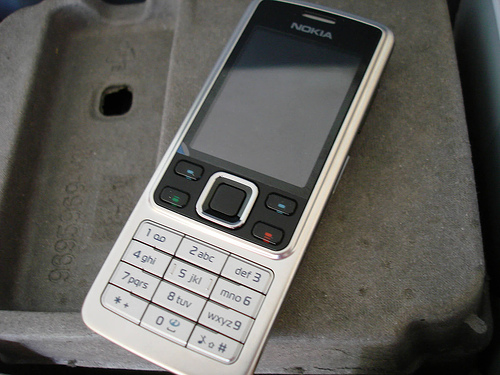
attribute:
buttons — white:
[118, 226, 325, 370]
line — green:
[146, 191, 214, 211]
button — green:
[149, 181, 196, 218]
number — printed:
[143, 224, 155, 241]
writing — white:
[287, 20, 335, 41]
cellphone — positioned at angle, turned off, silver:
[82, 4, 392, 371]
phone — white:
[140, 19, 335, 355]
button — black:
[208, 181, 247, 219]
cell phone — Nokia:
[79, 0, 393, 373]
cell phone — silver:
[105, 0, 497, 367]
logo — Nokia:
[291, 18, 334, 42]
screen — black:
[185, 21, 383, 191]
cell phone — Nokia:
[84, 71, 389, 356]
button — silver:
[212, 255, 291, 304]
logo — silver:
[289, 19, 333, 41]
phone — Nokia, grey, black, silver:
[78, 0, 395, 373]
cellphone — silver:
[155, 23, 497, 374]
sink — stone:
[9, 21, 449, 358]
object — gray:
[5, 15, 483, 345]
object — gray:
[18, 113, 138, 330]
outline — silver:
[188, 167, 268, 236]